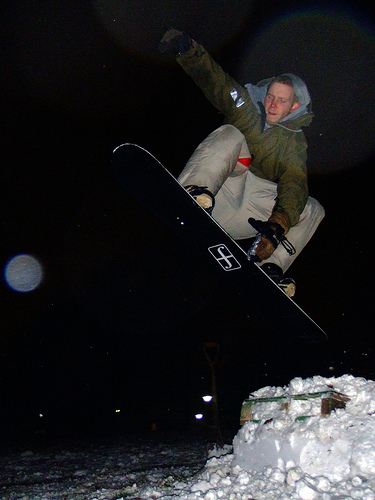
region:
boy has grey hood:
[252, 72, 312, 128]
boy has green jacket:
[180, 50, 315, 179]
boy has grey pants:
[195, 133, 323, 260]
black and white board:
[108, 147, 337, 362]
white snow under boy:
[250, 375, 372, 471]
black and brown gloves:
[241, 182, 293, 281]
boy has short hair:
[254, 67, 306, 103]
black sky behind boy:
[23, 1, 109, 90]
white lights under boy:
[174, 373, 229, 426]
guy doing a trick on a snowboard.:
[107, 27, 333, 344]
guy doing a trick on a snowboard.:
[111, 25, 337, 344]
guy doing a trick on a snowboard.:
[111, 24, 323, 340]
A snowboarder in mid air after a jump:
[105, 20, 338, 367]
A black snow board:
[110, 139, 330, 343]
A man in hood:
[255, 73, 308, 130]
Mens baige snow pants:
[181, 120, 325, 279]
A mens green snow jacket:
[183, 39, 311, 221]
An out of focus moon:
[4, 252, 43, 292]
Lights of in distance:
[25, 388, 232, 446]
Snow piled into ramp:
[207, 371, 374, 488]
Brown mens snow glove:
[246, 199, 291, 263]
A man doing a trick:
[105, 16, 336, 356]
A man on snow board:
[113, 45, 340, 333]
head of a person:
[258, 65, 301, 127]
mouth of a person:
[258, 109, 283, 119]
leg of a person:
[232, 230, 311, 292]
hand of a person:
[236, 212, 292, 270]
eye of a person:
[276, 93, 284, 104]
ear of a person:
[285, 95, 305, 121]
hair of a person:
[274, 73, 297, 82]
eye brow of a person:
[262, 83, 275, 96]